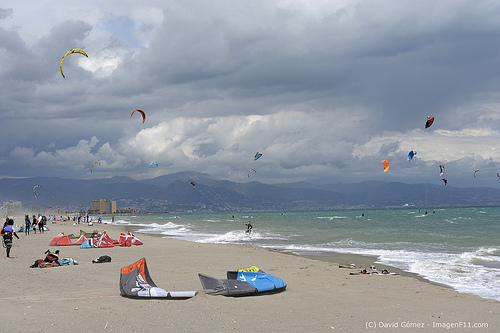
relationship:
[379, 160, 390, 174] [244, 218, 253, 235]
kite being used by a surfer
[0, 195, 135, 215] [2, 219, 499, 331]
buildings near beach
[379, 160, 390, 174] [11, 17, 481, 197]
kite in sky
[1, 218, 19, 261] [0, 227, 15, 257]
people holds kite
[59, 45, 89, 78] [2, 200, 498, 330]
sail over beach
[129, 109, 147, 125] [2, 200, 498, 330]
sail over beach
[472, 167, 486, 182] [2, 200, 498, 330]
sail over beach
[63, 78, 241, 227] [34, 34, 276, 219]
rope connected to sails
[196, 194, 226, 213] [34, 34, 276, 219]
rope connected to sails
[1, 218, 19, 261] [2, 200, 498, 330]
people on beach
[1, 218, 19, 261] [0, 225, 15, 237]
people in blue top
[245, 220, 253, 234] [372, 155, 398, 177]
kitesurfing man has kite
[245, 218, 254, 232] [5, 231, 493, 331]
kitesurfing man on shore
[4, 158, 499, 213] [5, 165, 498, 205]
mountain on background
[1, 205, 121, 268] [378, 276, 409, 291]
people on beach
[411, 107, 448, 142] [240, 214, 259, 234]
kite being used by surfer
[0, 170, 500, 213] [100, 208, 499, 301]
mountain near ocean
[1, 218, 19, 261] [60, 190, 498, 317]
people in ocean